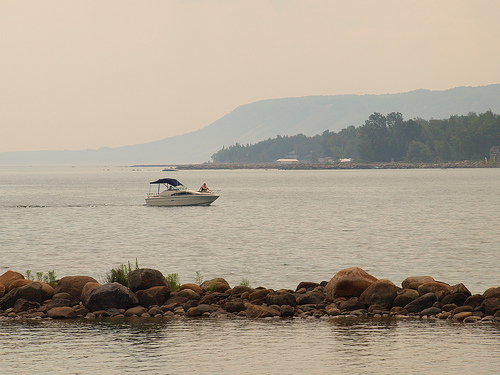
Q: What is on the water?
A: Boat.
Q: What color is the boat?
A: White.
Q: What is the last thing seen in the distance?
A: Mountains.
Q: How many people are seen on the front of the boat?
A: One.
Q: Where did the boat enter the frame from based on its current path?
A: Left.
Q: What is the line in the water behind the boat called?
A: Wake.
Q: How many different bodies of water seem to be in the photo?
A: Two.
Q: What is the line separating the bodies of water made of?
A: Rocks.